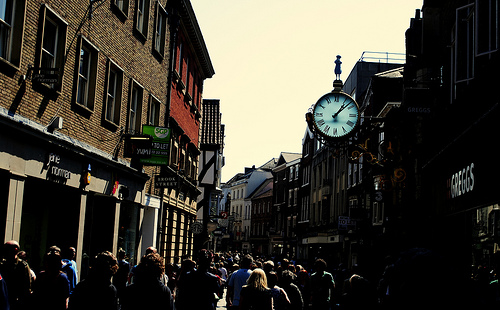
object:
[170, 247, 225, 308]
people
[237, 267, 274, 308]
person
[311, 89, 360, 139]
clock face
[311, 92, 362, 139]
face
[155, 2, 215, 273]
building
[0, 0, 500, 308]
photo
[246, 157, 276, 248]
building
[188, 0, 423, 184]
sky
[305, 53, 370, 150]
clock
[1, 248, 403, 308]
crowd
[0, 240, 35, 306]
people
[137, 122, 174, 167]
sign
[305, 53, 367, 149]
window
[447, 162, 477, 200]
sign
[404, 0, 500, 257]
building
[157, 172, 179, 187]
sign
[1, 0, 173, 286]
building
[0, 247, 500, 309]
street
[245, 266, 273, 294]
hair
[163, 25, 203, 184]
wall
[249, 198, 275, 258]
facade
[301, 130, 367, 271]
facade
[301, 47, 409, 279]
building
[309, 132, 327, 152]
bad sentence